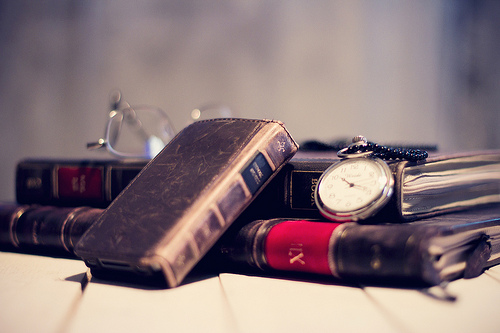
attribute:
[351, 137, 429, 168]
rope — blue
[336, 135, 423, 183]
watch chain — black, beaded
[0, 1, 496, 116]
wall — background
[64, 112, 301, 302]
bible — part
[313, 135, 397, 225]
watch — edge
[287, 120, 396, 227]
watch — antique, style, silver, pocket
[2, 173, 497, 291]
book — leather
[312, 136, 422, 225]
watch — stop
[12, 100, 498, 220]
book — edge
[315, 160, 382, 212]
numbers — black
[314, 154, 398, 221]
clock — part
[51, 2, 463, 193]
background — blurry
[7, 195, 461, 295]
roun spine — rounded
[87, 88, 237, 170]
eyeglasses — silver, frames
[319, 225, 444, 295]
book — edge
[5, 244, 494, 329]
table — wooden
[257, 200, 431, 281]
book — red, brown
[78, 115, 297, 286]
book — small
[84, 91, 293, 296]
bible — edge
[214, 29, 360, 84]
wall — grey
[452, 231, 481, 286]
mark — black, book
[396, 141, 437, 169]
band — black, watch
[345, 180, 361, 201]
hands — black, clock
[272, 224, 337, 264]
jacket — red, brown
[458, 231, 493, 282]
book mark — brown, ribbon